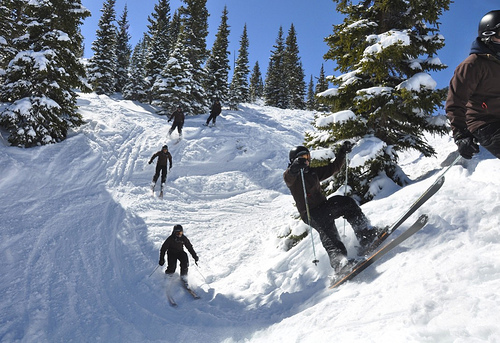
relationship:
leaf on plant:
[337, 40, 354, 54] [356, 20, 421, 119]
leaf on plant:
[306, 64, 441, 129] [330, 20, 415, 120]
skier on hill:
[445, 10, 498, 160] [5, 84, 499, 334]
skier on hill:
[284, 140, 386, 274] [5, 84, 499, 334]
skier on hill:
[158, 223, 198, 296] [5, 84, 499, 334]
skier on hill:
[149, 145, 172, 188] [5, 84, 499, 334]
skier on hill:
[166, 104, 185, 139] [5, 84, 499, 334]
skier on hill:
[206, 95, 223, 125] [5, 84, 499, 334]